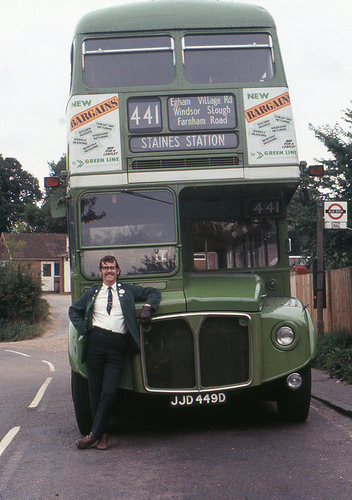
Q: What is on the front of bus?
A: Windshield.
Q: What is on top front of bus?
A: Windshields.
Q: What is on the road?
A: White line.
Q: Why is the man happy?
A: He's going somewhere.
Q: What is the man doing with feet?
A: Crossed them.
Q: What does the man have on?
A: Tight pants.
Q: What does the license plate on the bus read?
A: JJD449D.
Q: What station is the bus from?
A: Staines station.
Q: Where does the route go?
A: Egham village road, windsor slough, farnham road.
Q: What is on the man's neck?
A: A tie.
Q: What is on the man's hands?
A: Gloves.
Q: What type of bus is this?
A: Double decker.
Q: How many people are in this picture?
A: One.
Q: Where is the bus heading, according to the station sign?
A: Staines Station.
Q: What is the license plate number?
A: JJD449D.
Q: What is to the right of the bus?
A: A fence.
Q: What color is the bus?
A: Green.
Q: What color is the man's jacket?
A: Dark green.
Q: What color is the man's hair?
A: Brown.